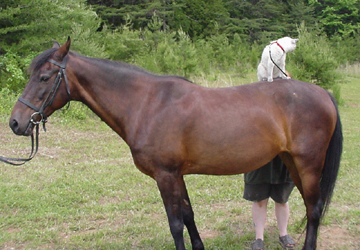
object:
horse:
[8, 35, 344, 249]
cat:
[256, 35, 297, 85]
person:
[244, 155, 296, 249]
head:
[9, 34, 71, 137]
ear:
[53, 36, 72, 62]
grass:
[1, 62, 358, 249]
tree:
[170, 2, 233, 43]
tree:
[0, 0, 109, 104]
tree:
[92, 0, 166, 31]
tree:
[315, 2, 347, 45]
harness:
[0, 53, 69, 167]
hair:
[29, 45, 58, 71]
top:
[26, 34, 109, 80]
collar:
[276, 41, 286, 53]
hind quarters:
[271, 78, 343, 249]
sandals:
[276, 233, 298, 250]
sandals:
[250, 238, 265, 249]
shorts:
[241, 181, 296, 205]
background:
[0, 1, 359, 130]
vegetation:
[1, 0, 360, 120]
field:
[0, 39, 357, 249]